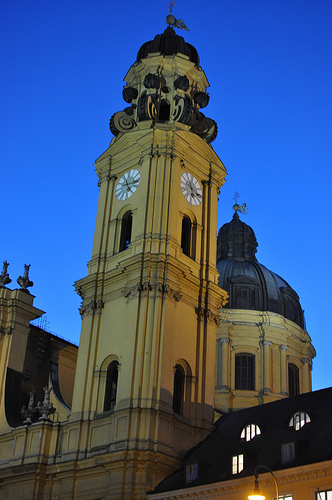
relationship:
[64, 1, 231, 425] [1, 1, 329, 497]
tower part of building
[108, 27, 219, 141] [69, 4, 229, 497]
roof on tower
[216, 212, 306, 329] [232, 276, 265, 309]
roof on room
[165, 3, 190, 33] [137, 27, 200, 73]
weather meter on roof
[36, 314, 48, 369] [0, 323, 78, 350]
ladder leading to roof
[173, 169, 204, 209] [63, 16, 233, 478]
clock on tower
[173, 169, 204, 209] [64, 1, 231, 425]
clock on tower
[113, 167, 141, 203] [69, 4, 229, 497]
clock on tower